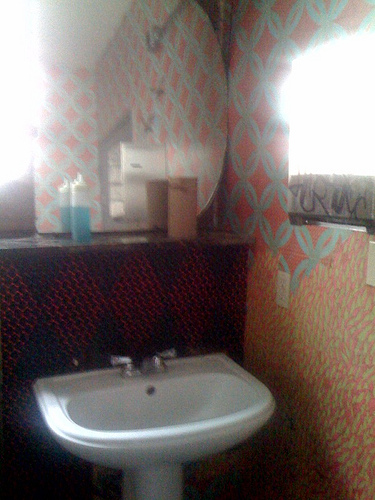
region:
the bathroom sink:
[9, 16, 363, 498]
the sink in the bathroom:
[35, 339, 276, 456]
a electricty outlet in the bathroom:
[248, 236, 314, 326]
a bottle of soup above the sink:
[52, 172, 127, 255]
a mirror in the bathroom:
[78, 27, 291, 174]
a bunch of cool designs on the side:
[224, 25, 289, 247]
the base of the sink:
[105, 470, 214, 498]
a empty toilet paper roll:
[151, 171, 207, 259]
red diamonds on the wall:
[34, 255, 233, 349]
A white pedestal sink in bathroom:
[44, 360, 272, 496]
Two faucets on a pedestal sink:
[110, 349, 179, 374]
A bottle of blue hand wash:
[68, 177, 98, 243]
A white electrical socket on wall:
[277, 274, 289, 310]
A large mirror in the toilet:
[7, 4, 220, 231]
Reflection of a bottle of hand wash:
[60, 180, 71, 234]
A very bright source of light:
[286, 7, 373, 178]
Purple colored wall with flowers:
[1, 248, 247, 366]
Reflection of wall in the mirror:
[40, 2, 223, 147]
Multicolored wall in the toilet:
[278, 331, 374, 490]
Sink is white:
[22, 337, 281, 498]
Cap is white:
[69, 170, 89, 193]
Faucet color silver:
[140, 350, 170, 377]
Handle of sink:
[106, 347, 131, 367]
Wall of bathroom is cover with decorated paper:
[8, 0, 371, 497]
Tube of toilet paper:
[159, 162, 199, 244]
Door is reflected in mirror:
[82, 102, 138, 229]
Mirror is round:
[0, 0, 233, 230]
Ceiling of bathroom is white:
[18, 0, 101, 60]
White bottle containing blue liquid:
[64, 169, 100, 248]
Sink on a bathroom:
[22, 334, 282, 499]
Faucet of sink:
[137, 349, 170, 381]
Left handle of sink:
[102, 341, 145, 381]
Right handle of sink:
[157, 341, 183, 366]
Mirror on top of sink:
[0, 0, 233, 224]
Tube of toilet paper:
[159, 166, 204, 239]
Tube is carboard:
[161, 171, 206, 244]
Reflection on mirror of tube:
[142, 169, 169, 234]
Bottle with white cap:
[66, 164, 98, 242]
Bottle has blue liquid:
[67, 167, 95, 248]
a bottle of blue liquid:
[58, 169, 107, 246]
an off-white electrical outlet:
[269, 263, 299, 313]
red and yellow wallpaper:
[283, 324, 354, 459]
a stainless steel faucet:
[99, 340, 182, 381]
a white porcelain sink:
[30, 333, 279, 487]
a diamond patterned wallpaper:
[0, 253, 264, 350]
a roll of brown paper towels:
[156, 156, 210, 248]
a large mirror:
[4, 3, 255, 270]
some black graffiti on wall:
[280, 166, 371, 231]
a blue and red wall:
[217, 0, 302, 257]